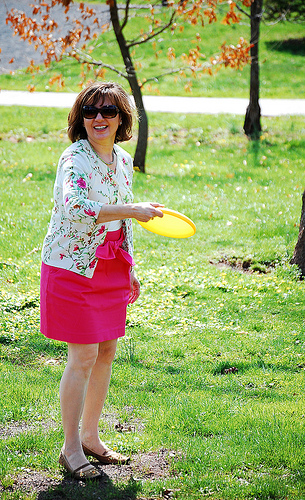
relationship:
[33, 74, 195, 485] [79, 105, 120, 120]
lady wearing sunglasses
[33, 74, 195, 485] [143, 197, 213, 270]
lady holding frisbee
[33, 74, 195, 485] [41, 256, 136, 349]
lady wearing skirt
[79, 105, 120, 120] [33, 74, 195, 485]
sunglasses on lady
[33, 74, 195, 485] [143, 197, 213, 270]
lady playing frisbee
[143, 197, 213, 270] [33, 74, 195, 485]
frisbee with lady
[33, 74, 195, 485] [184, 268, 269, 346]
lady on grass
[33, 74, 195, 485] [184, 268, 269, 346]
lady in grass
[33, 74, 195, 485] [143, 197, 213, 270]
lady with frisbee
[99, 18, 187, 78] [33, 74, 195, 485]
tree near lady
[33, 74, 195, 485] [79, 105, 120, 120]
lady wears sunglasses